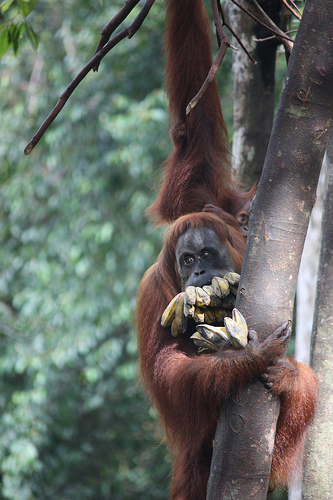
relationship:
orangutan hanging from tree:
[134, 0, 321, 500] [204, 0, 333, 500]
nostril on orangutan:
[194, 271, 200, 277] [134, 0, 321, 500]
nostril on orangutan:
[199, 269, 207, 277] [134, 0, 321, 500]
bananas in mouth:
[158, 272, 243, 339] [180, 271, 238, 301]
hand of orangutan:
[245, 320, 303, 366] [134, 0, 321, 500]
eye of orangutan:
[201, 249, 213, 259] [134, 0, 321, 500]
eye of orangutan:
[182, 255, 194, 265] [134, 0, 321, 500]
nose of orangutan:
[191, 260, 207, 277] [134, 0, 321, 500]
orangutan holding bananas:
[134, 0, 321, 500] [158, 272, 243, 339]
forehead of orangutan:
[168, 225, 221, 256] [134, 0, 321, 500]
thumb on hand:
[245, 327, 261, 342] [245, 320, 303, 366]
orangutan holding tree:
[134, 0, 321, 500] [204, 0, 333, 500]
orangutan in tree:
[134, 0, 321, 500] [204, 0, 333, 500]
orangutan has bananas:
[134, 0, 321, 500] [158, 272, 243, 339]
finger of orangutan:
[275, 318, 291, 338] [134, 0, 321, 500]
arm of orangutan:
[157, 331, 281, 404] [134, 0, 321, 500]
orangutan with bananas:
[134, 0, 321, 500] [158, 272, 243, 339]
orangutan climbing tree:
[134, 0, 321, 500] [204, 0, 333, 500]